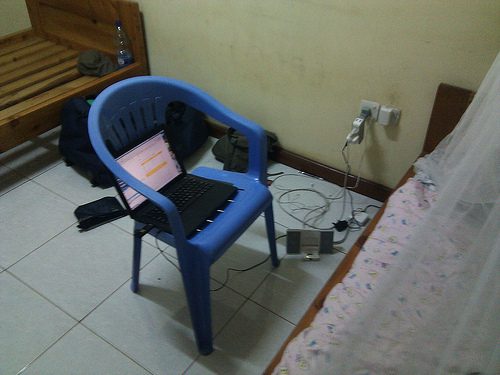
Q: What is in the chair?
A: Laptop.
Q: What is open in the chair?
A: Laptop.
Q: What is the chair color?
A: Blue.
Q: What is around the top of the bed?
A: Lace.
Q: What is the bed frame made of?
A: Wood.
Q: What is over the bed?
A: Tulle.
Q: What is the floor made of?
A: Tile.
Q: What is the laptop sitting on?
A: A blue plastic chair.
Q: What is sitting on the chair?
A: A laptop.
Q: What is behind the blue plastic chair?
A: A wooden bed frame.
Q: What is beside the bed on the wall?
A: An electrical outlet.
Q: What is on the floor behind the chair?
A: A black purse.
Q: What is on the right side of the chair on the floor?
A: Wires.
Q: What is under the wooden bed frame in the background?
A: A shadow.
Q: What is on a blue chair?
A: Laptop.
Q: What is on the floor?
A: Square tiles.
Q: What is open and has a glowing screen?
A: Laptop.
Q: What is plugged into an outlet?
A: Wires.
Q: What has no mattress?
A: Bed frame.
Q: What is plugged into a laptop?
A: Wire.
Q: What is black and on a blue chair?
A: A laptop.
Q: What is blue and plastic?
A: A chair.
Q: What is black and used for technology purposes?
A: A laptop computer.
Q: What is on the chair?
A: Laptop.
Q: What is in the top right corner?
A: Bed frame.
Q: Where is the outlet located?
A: On the wall.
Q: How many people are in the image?
A: 0.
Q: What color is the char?
A: Blue.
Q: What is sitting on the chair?
A: Laptop.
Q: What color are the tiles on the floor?
A: White.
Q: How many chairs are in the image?
A: 1.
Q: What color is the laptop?
A: Black.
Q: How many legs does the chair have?
A: 4.